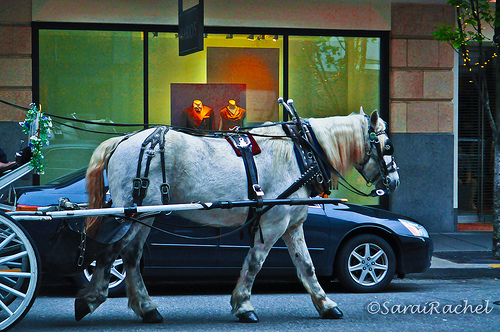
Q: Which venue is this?
A: This is a store.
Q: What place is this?
A: It is a store.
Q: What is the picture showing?
A: It is showing a store.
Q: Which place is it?
A: It is a store.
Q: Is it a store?
A: Yes, it is a store.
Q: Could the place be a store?
A: Yes, it is a store.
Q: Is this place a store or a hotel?
A: It is a store.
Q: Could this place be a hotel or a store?
A: It is a store.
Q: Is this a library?
A: No, it is a store.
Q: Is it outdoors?
A: Yes, it is outdoors.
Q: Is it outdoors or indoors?
A: It is outdoors.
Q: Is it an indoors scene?
A: No, it is outdoors.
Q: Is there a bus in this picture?
A: No, there are no buses.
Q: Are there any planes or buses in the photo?
A: No, there are no buses or planes.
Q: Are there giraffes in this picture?
A: No, there are no giraffes.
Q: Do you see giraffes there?
A: No, there are no giraffes.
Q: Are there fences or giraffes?
A: No, there are no giraffes or fences.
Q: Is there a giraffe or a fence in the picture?
A: No, there are no giraffes or fences.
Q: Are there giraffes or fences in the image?
A: No, there are no giraffes or fences.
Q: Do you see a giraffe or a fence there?
A: No, there are no giraffes or fences.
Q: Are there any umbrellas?
A: No, there are no umbrellas.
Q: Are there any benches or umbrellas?
A: No, there are no umbrellas or benches.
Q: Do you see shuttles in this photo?
A: No, there are no shuttles.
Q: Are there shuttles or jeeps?
A: No, there are no shuttles or jeeps.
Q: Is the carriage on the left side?
A: Yes, the carriage is on the left of the image.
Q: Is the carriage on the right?
A: No, the carriage is on the left of the image.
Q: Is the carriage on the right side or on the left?
A: The carriage is on the left of the image.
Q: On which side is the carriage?
A: The carriage is on the left of the image.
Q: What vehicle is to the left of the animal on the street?
A: The vehicle is a carriage.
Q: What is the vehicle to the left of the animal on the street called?
A: The vehicle is a carriage.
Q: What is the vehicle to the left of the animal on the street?
A: The vehicle is a carriage.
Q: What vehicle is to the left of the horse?
A: The vehicle is a carriage.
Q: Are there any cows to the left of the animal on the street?
A: No, there is a carriage to the left of the horse.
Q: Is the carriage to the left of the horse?
A: Yes, the carriage is to the left of the horse.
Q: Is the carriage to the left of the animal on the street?
A: Yes, the carriage is to the left of the horse.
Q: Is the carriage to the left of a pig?
A: No, the carriage is to the left of the horse.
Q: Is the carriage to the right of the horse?
A: No, the carriage is to the left of the horse.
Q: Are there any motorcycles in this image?
A: No, there are no motorcycles.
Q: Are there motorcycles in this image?
A: No, there are no motorcycles.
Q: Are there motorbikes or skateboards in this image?
A: No, there are no motorbikes or skateboards.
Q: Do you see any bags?
A: No, there are no bags.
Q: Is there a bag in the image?
A: No, there are no bags.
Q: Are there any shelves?
A: No, there are no shelves.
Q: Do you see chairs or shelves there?
A: No, there are no shelves or chairs.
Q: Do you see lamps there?
A: No, there are no lamps.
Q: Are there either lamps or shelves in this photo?
A: No, there are no lamps or shelves.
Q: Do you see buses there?
A: No, there are no buses.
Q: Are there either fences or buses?
A: No, there are no buses or fences.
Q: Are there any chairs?
A: No, there are no chairs.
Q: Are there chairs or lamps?
A: No, there are no chairs or lamps.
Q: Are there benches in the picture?
A: No, there are no benches.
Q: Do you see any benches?
A: No, there are no benches.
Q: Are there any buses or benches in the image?
A: No, there are no benches or buses.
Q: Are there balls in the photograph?
A: No, there are no balls.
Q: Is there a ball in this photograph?
A: No, there are no balls.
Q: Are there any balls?
A: No, there are no balls.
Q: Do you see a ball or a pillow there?
A: No, there are no balls or pillows.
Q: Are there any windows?
A: Yes, there is a window.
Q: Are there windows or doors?
A: Yes, there is a window.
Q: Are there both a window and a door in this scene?
A: No, there is a window but no doors.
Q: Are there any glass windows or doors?
A: Yes, there is a glass window.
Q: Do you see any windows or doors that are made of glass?
A: Yes, the window is made of glass.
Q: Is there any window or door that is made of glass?
A: Yes, the window is made of glass.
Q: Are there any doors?
A: No, there are no doors.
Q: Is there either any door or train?
A: No, there are no doors or trains.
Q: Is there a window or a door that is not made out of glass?
A: No, there is a window but it is made of glass.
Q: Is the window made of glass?
A: Yes, the window is made of glass.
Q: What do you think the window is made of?
A: The window is made of glass.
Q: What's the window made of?
A: The window is made of glass.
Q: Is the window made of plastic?
A: No, the window is made of glass.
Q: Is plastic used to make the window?
A: No, the window is made of glass.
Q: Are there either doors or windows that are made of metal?
A: No, there is a window but it is made of glass.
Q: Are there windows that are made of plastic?
A: No, there is a window but it is made of glass.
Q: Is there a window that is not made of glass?
A: No, there is a window but it is made of glass.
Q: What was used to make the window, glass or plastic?
A: The window is made of glass.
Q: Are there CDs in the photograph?
A: No, there are no cds.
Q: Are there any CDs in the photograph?
A: No, there are no cds.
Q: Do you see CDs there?
A: No, there are no cds.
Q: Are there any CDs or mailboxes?
A: No, there are no CDs or mailboxes.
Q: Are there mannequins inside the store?
A: Yes, there are mannequins inside the store.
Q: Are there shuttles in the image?
A: No, there are no shuttles.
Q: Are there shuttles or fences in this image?
A: No, there are no shuttles or fences.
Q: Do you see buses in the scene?
A: No, there are no buses.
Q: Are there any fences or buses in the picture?
A: No, there are no buses or fences.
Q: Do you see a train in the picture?
A: No, there are no trains.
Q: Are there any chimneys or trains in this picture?
A: No, there are no trains or chimneys.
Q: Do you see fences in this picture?
A: No, there are no fences.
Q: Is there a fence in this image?
A: No, there are no fences.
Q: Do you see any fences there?
A: No, there are no fences.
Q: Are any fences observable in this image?
A: No, there are no fences.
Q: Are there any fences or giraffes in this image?
A: No, there are no fences or giraffes.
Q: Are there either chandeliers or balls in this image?
A: No, there are no balls or chandeliers.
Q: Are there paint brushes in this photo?
A: No, there are no paint brushes.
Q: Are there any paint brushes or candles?
A: No, there are no paint brushes or candles.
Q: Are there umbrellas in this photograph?
A: No, there are no umbrellas.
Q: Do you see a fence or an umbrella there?
A: No, there are no umbrellas or fences.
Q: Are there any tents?
A: No, there are no tents.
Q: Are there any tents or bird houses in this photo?
A: No, there are no tents or bird houses.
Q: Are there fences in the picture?
A: No, there are no fences.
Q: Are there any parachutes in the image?
A: No, there are no parachutes.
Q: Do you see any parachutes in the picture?
A: No, there are no parachutes.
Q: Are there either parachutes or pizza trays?
A: No, there are no parachutes or pizza trays.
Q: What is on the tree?
A: The Christmas lights are on the tree.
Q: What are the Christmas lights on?
A: The Christmas lights are on the tree.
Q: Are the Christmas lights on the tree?
A: Yes, the Christmas lights are on the tree.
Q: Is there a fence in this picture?
A: No, there are no fences.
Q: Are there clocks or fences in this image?
A: No, there are no fences or clocks.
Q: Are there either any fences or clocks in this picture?
A: No, there are no fences or clocks.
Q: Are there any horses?
A: Yes, there is a horse.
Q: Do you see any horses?
A: Yes, there is a horse.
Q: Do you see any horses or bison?
A: Yes, there is a horse.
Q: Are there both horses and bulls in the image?
A: No, there is a horse but no bulls.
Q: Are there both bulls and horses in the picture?
A: No, there is a horse but no bulls.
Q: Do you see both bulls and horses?
A: No, there is a horse but no bulls.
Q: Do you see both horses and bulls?
A: No, there is a horse but no bulls.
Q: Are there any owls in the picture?
A: No, there are no owls.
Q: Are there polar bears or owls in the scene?
A: No, there are no owls or polar bears.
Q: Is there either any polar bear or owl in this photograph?
A: No, there are no owls or polar bears.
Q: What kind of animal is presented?
A: The animal is a horse.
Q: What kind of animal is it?
A: The animal is a horse.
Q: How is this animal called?
A: This is a horse.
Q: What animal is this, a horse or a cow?
A: This is a horse.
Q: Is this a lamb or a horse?
A: This is a horse.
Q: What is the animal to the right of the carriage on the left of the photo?
A: The animal is a horse.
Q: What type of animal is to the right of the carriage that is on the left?
A: The animal is a horse.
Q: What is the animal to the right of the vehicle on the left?
A: The animal is a horse.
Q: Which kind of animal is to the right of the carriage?
A: The animal is a horse.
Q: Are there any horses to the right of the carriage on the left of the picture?
A: Yes, there is a horse to the right of the carriage.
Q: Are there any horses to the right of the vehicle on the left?
A: Yes, there is a horse to the right of the carriage.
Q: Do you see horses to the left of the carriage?
A: No, the horse is to the right of the carriage.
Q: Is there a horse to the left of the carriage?
A: No, the horse is to the right of the carriage.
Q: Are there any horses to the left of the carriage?
A: No, the horse is to the right of the carriage.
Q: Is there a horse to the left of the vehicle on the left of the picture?
A: No, the horse is to the right of the carriage.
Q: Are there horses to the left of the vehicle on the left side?
A: No, the horse is to the right of the carriage.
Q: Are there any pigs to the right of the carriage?
A: No, there is a horse to the right of the carriage.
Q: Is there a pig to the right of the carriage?
A: No, there is a horse to the right of the carriage.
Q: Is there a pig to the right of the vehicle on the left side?
A: No, there is a horse to the right of the carriage.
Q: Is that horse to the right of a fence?
A: No, the horse is to the right of the carriage.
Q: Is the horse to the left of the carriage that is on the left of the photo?
A: No, the horse is to the right of the carriage.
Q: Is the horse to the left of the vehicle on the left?
A: No, the horse is to the right of the carriage.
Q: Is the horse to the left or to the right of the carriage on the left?
A: The horse is to the right of the carriage.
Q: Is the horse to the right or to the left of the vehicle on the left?
A: The horse is to the right of the carriage.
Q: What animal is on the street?
A: The horse is on the street.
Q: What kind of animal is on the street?
A: The animal is a horse.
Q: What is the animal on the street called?
A: The animal is a horse.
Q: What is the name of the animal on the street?
A: The animal is a horse.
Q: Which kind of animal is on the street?
A: The animal is a horse.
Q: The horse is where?
A: The horse is on the street.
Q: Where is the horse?
A: The horse is on the street.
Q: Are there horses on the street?
A: Yes, there is a horse on the street.